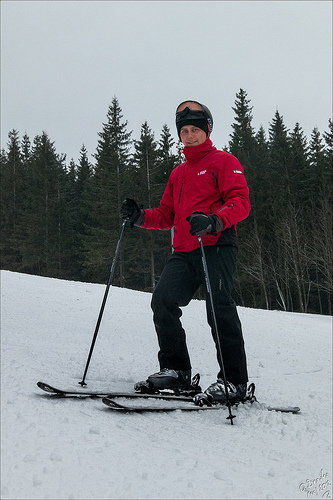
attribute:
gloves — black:
[118, 197, 219, 237]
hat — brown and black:
[176, 101, 211, 137]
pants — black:
[156, 235, 247, 343]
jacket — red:
[151, 151, 267, 217]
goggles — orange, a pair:
[174, 98, 206, 115]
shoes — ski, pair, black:
[133, 363, 249, 404]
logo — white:
[230, 165, 248, 179]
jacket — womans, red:
[139, 138, 251, 252]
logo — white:
[183, 198, 225, 237]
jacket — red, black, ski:
[131, 135, 251, 250]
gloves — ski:
[108, 192, 220, 240]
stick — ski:
[80, 214, 130, 386]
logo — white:
[25, 381, 66, 428]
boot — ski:
[193, 370, 249, 406]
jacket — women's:
[133, 142, 253, 254]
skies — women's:
[34, 377, 301, 421]